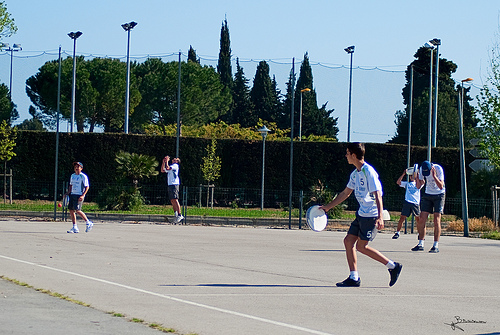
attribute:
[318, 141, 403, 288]
man — light skinned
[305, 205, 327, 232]
frisbee — white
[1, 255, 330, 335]
line — solid, white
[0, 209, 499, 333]
playground — tarmacked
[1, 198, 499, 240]
grass — green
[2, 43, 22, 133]
pole — long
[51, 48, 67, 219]
pole — long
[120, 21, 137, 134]
pole — long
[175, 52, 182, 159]
pole — long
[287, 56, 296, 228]
pole — long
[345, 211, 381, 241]
shorts — black, blue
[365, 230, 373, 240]
number — five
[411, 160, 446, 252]
man — light skinned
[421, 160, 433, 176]
cap — blue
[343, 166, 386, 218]
shirt — white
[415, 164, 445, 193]
shirt — white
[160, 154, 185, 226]
man — jumping, light skinned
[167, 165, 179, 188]
shirt — white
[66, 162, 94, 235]
man — light skinned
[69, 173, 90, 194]
shirt — white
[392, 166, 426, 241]
man — light skinned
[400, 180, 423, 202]
shirt — white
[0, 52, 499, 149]
netting — clear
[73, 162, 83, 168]
cap — blue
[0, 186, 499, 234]
fence — metal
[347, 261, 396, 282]
socks — white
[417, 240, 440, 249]
socks — white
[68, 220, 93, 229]
socks — white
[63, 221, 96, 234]
shoes — white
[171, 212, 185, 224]
shoes — white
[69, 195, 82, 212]
shorts — blue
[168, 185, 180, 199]
shorts — blue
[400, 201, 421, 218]
shorts — blue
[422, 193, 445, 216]
shorts — blue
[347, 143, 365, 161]
hair — brown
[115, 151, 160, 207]
bush — green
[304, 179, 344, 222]
bush — green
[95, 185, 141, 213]
bush — green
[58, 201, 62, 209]
ball — orange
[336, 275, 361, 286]
sneaker — black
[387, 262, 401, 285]
sneaker — black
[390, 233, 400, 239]
sneaker — black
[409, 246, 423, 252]
sneaker — black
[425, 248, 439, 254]
sneaker — black